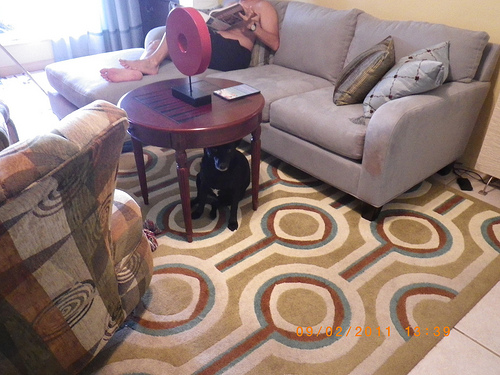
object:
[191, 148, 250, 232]
dog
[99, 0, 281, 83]
person reading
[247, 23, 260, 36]
watch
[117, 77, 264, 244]
table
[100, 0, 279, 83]
person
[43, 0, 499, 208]
couch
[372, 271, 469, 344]
rug pattern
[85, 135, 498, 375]
rug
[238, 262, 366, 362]
pattern